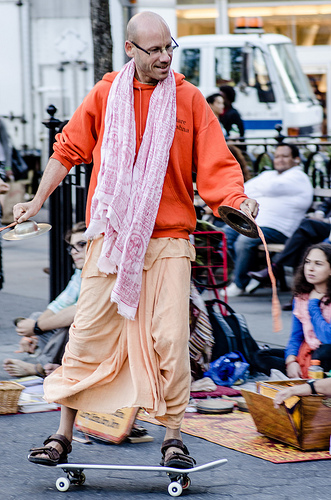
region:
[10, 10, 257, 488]
Man riding a skaterboard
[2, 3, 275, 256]
Man holding symbols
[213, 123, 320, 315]
Man sitting on chair with arms folded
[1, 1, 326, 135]
Truck in the background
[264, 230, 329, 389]
woman sitting on the ground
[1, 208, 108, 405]
Man with glasses sitting on the ground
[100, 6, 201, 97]
Bald man wearing glasses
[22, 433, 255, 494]
Skateboard being ridden by man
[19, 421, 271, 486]
Sandals on the skateboard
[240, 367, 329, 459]
Hand wearing wristwatch on wooden crate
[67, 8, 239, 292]
man is wearing scarf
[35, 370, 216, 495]
man is riding a skateboard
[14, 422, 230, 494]
the sandals are brown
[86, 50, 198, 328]
the scarf is pink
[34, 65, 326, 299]
the jacket is orange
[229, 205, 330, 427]
a woman sitting on the ground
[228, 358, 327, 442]
the box is made of wood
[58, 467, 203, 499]
the wheels are white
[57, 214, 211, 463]
the skirt is peach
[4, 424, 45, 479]
the ground is gray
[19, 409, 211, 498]
the skate board is white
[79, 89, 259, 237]
the top is orange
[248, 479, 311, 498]
the road is grey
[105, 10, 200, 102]
the head is bad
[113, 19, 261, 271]
the guy has glasses on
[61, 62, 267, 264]
the man is wearing scarf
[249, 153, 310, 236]
the guy is sitted down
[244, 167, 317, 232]
the guy has a white top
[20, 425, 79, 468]
brown men's sandals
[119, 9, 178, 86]
bald mans head with glasses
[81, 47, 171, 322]
pink and white scraf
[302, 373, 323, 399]
black wrist watch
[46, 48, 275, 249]
orange men's hootie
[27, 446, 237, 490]
rollerblade with white wheels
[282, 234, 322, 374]
woman with brunette hair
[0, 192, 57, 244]
hand holding bell in bronze color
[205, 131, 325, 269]
middle age man sitting on a bench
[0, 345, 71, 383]
barefoot leg with toes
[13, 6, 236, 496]
mam on a skateboard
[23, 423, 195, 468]
man wearing sandals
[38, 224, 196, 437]
man wearing loose fitting skirt-like garment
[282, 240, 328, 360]
woman holding her hand near her throat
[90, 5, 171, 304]
long scarf around man's neck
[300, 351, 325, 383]
plastic bottle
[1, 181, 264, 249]
man holding cymbals in his hands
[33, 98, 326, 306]
black railing behind man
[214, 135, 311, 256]
man in white shirt sitting in the background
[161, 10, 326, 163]
blue and white vehicle in background